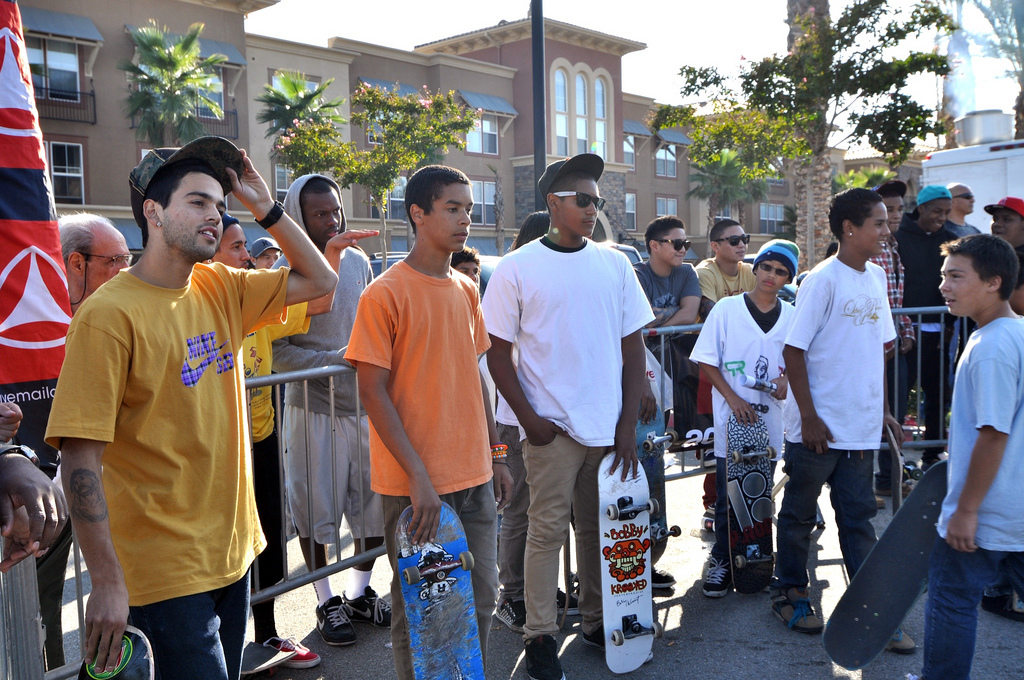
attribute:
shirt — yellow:
[46, 266, 310, 606]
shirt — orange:
[339, 264, 507, 492]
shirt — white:
[487, 236, 653, 443]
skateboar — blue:
[392, 500, 481, 669]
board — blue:
[589, 467, 678, 657]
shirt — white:
[95, 292, 326, 571]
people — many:
[144, 234, 522, 451]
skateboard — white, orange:
[592, 450, 660, 675]